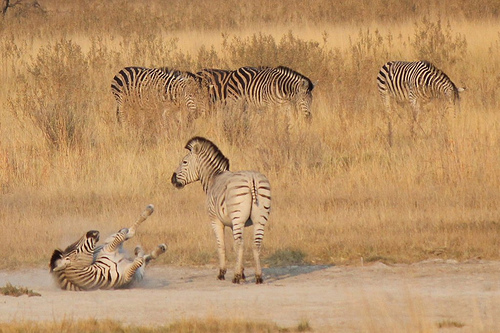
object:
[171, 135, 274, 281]
zebra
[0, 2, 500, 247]
ground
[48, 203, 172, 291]
zebra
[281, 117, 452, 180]
weeds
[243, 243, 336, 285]
shadow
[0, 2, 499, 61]
grass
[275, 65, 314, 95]
hairs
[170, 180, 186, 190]
zebra mouth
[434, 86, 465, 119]
zebrashead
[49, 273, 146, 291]
back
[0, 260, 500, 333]
path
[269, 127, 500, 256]
grassland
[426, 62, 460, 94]
mane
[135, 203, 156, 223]
hooves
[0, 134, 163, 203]
air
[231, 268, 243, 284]
hooves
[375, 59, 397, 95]
zebrarear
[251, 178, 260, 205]
tail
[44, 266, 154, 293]
side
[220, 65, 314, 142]
zebras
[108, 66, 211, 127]
zebra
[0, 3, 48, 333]
left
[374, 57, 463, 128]
zebra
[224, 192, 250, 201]
stripes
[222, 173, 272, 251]
hindquarters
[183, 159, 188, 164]
eyes